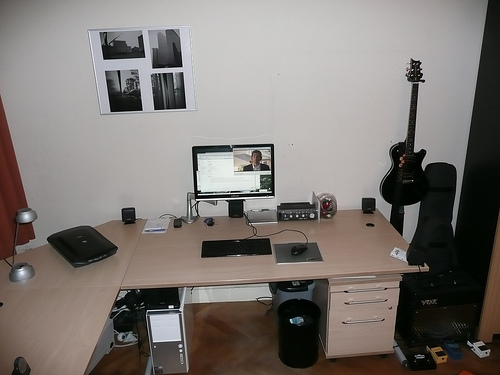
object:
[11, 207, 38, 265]
lamp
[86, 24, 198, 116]
frame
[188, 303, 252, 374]
floor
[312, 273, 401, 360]
drawer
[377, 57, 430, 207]
guitar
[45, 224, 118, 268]
scanner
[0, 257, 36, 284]
desk lamp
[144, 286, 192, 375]
computer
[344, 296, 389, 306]
handle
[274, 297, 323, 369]
can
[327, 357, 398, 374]
floor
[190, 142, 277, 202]
screen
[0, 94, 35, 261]
curtain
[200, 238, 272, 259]
keyboard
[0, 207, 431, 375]
desk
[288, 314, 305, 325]
paper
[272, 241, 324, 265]
mouse pad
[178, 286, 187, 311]
computer tower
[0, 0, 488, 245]
wall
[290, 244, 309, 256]
computer mouse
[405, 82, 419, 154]
neck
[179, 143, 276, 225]
computer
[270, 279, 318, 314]
paper shredder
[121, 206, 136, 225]
speaker